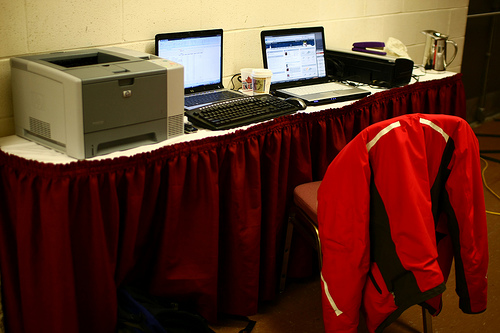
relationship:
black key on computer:
[207, 115, 219, 117] [153, 23, 300, 128]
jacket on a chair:
[315, 110, 496, 331] [283, 118, 484, 330]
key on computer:
[209, 109, 214, 113] [155, 35, 280, 131]